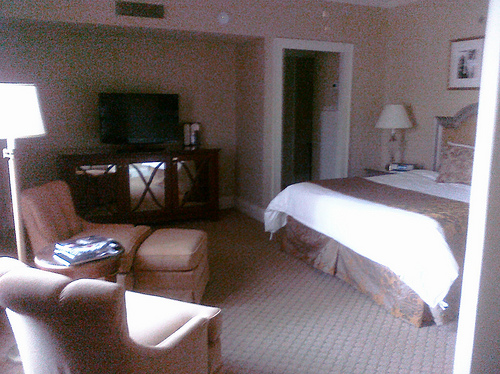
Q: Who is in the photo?
A: Nobody.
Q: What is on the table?
A: Magazines.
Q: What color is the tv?
A: Black.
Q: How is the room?
A: Tidy.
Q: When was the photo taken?
A: Daytime.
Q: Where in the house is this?
A: Bedroom.